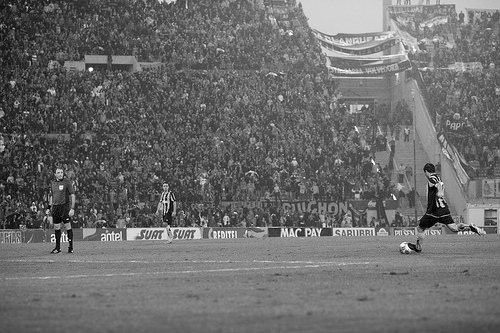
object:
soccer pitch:
[0, 227, 497, 333]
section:
[0, 234, 500, 333]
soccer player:
[405, 162, 483, 255]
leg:
[409, 215, 437, 250]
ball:
[398, 241, 415, 254]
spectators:
[455, 9, 469, 22]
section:
[383, 2, 499, 182]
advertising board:
[0, 226, 499, 245]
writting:
[280, 228, 325, 238]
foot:
[469, 223, 485, 237]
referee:
[45, 166, 78, 255]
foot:
[50, 247, 62, 255]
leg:
[62, 207, 74, 251]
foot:
[407, 242, 422, 253]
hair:
[423, 162, 436, 173]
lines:
[0, 260, 375, 280]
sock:
[66, 229, 74, 248]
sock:
[54, 229, 61, 249]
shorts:
[50, 203, 72, 223]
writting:
[135, 228, 196, 240]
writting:
[212, 230, 238, 240]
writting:
[47, 230, 125, 242]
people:
[114, 68, 125, 79]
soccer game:
[0, 162, 499, 331]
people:
[135, 105, 147, 117]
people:
[162, 71, 172, 83]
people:
[171, 98, 182, 105]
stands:
[0, 1, 406, 226]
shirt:
[159, 190, 177, 217]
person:
[155, 181, 176, 243]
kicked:
[398, 217, 486, 255]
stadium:
[0, 2, 497, 331]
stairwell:
[349, 117, 413, 228]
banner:
[311, 27, 401, 49]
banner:
[328, 60, 411, 77]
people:
[389, 136, 396, 159]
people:
[404, 126, 410, 142]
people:
[396, 163, 406, 184]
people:
[406, 187, 420, 209]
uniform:
[418, 175, 454, 230]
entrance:
[85, 56, 140, 72]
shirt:
[423, 175, 451, 220]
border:
[0, 214, 467, 229]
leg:
[444, 214, 470, 235]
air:
[0, 0, 499, 333]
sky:
[300, 0, 387, 34]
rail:
[372, 123, 427, 214]